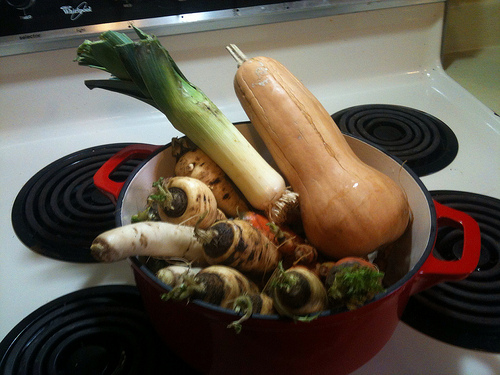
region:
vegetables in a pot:
[65, 6, 489, 367]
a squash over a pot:
[220, 33, 407, 276]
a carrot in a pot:
[323, 231, 387, 311]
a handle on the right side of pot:
[411, 195, 484, 287]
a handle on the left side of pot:
[88, 131, 167, 196]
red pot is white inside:
[126, 120, 438, 292]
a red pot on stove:
[8, 5, 495, 371]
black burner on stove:
[338, 82, 468, 177]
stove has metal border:
[0, 0, 440, 62]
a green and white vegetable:
[83, 18, 295, 229]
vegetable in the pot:
[217, 233, 280, 272]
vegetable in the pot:
[279, 273, 339, 313]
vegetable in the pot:
[246, 296, 266, 313]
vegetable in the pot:
[331, 259, 373, 297]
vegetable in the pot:
[193, 269, 232, 291]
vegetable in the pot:
[103, 227, 185, 259]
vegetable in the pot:
[150, 185, 220, 222]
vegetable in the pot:
[252, 80, 387, 250]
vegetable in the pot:
[189, 119, 281, 217]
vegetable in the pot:
[172, 148, 221, 188]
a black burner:
[378, 112, 435, 148]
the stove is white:
[6, 270, 51, 300]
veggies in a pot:
[208, 220, 310, 305]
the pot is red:
[294, 330, 356, 370]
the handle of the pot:
[443, 236, 482, 268]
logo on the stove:
[58, 2, 98, 19]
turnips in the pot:
[146, 175, 235, 226]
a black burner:
[31, 320, 104, 358]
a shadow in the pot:
[388, 238, 410, 275]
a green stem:
[100, 43, 190, 88]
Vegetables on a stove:
[4, 6, 499, 374]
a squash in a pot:
[216, 28, 401, 248]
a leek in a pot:
[74, 26, 281, 213]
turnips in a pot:
[156, 158, 277, 301]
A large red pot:
[97, 104, 499, 374]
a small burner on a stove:
[345, 94, 456, 162]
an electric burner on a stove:
[330, 98, 457, 180]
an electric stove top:
[22, 78, 496, 370]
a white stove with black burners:
[8, 10, 497, 351]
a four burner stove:
[1, 91, 497, 372]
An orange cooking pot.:
[93, 119, 481, 374]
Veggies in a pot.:
[71, 24, 482, 374]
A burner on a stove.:
[10, 140, 165, 262]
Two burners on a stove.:
[2, 142, 199, 373]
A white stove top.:
[3, 2, 495, 373]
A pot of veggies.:
[73, 25, 482, 370]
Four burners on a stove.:
[3, 103, 498, 374]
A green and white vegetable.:
[74, 23, 300, 227]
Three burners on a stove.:
[10, 102, 499, 355]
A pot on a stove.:
[92, 121, 483, 368]